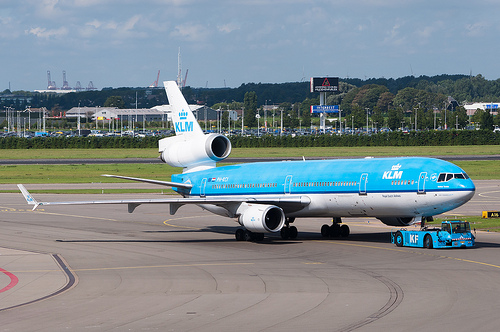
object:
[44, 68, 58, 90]
cranes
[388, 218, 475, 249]
ground equipment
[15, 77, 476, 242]
airplane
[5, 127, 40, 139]
parked cars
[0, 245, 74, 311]
stripe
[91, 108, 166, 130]
building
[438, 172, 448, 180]
windshield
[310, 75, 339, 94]
sign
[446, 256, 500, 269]
line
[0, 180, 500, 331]
street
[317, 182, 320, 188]
window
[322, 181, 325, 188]
window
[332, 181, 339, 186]
window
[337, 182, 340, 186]
window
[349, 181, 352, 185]
window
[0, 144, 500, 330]
ground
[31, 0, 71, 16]
cloud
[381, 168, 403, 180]
logo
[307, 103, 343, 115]
sign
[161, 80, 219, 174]
tail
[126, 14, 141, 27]
clouds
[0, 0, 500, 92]
sky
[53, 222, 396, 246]
shadow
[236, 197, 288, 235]
engine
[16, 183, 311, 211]
wing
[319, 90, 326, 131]
post